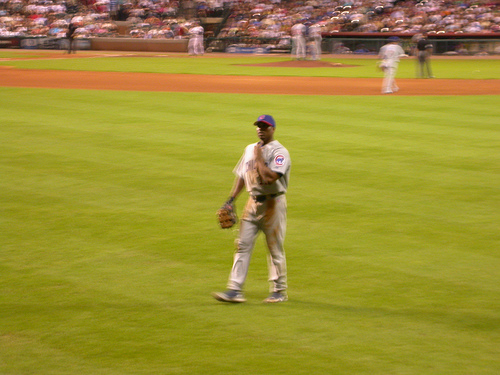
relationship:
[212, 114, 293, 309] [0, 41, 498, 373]
baseball player on baseball field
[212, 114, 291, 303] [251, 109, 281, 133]
baseball player wearing cap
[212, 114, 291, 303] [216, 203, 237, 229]
baseball player wearing gloves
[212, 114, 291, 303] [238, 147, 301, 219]
baseball player wearing uniform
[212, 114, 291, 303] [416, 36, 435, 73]
baseball player wearing clothes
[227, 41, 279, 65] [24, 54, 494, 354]
advertisement on baseball field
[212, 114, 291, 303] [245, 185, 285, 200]
baseball player wearing belt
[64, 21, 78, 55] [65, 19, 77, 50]
man wearing clothes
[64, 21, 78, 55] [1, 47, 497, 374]
man standing on field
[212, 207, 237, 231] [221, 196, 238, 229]
gloves in hand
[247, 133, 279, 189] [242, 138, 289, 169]
arm leaning against chest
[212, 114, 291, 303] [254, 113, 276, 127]
baseball player has cap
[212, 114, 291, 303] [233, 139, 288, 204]
baseball player in shirt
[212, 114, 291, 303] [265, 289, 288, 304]
baseball player in shoe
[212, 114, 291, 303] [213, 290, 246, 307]
baseball player in shoe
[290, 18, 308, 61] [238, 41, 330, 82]
baseball player standing on mound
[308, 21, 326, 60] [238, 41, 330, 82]
baseball player standing on mound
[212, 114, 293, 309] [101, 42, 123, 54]
baseball player walking towards home plate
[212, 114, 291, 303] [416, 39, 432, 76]
baseball player dressed in clothes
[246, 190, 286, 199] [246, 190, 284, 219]
belt has buckle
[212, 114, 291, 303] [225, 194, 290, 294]
baseball player has pants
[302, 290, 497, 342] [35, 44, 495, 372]
shadow in grass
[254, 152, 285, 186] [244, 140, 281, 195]
arm touching chest